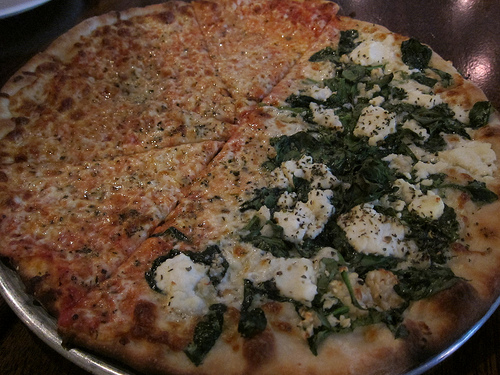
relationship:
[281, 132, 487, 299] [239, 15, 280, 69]
piece of pizza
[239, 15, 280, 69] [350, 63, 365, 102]
pizza has spinach on it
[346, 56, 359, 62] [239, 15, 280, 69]
spinach on pizza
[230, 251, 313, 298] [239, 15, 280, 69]
ricotta cheese on pizza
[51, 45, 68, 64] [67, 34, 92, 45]
part of crust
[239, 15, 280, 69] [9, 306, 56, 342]
pizza on pizza tray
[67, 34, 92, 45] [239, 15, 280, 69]
crust of pizza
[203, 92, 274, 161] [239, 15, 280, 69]
center of pizza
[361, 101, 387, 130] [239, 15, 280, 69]
spices on pizza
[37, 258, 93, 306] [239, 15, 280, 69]
tomato sauce on pizza